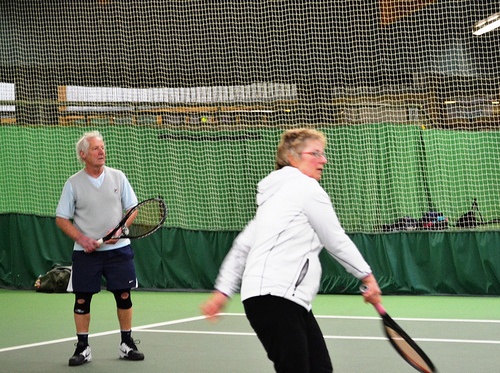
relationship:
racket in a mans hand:
[91, 204, 168, 246] [73, 228, 132, 264]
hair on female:
[273, 127, 326, 169] [199, 128, 382, 373]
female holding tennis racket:
[199, 128, 382, 373] [357, 285, 437, 371]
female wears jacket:
[199, 128, 382, 373] [218, 170, 370, 313]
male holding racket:
[55, 130, 144, 365] [85, 179, 169, 261]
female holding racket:
[199, 128, 382, 373] [85, 179, 169, 261]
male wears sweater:
[55, 130, 144, 365] [67, 165, 132, 252]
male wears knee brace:
[55, 130, 144, 365] [71, 292, 91, 314]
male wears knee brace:
[55, 130, 144, 365] [115, 289, 135, 306]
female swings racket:
[199, 128, 382, 373] [359, 284, 437, 373]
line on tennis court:
[215, 312, 499, 323] [4, 281, 498, 368]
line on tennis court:
[133, 329, 499, 344] [4, 281, 498, 368]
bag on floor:
[33, 263, 71, 293] [0, 289, 499, 372]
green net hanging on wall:
[0, 0, 500, 232] [0, 0, 490, 291]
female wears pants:
[199, 128, 382, 373] [233, 285, 347, 372]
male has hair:
[55, 130, 144, 365] [79, 125, 90, 159]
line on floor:
[1, 314, 218, 354] [0, 289, 499, 371]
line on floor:
[137, 327, 499, 345] [0, 289, 499, 371]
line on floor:
[221, 311, 499, 323] [0, 289, 499, 371]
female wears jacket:
[199, 128, 382, 373] [204, 155, 359, 285]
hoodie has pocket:
[212, 166, 373, 313] [289, 257, 313, 300]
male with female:
[55, 130, 144, 365] [199, 128, 382, 373]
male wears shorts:
[55, 130, 144, 365] [68, 247, 139, 292]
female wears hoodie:
[199, 128, 382, 373] [264, 169, 334, 307]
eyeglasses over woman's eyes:
[298, 150, 328, 158] [268, 143, 330, 158]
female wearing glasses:
[199, 128, 382, 373] [291, 144, 331, 166]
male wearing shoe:
[55, 130, 144, 365] [112, 334, 147, 363]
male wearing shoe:
[55, 130, 144, 365] [61, 338, 94, 365]